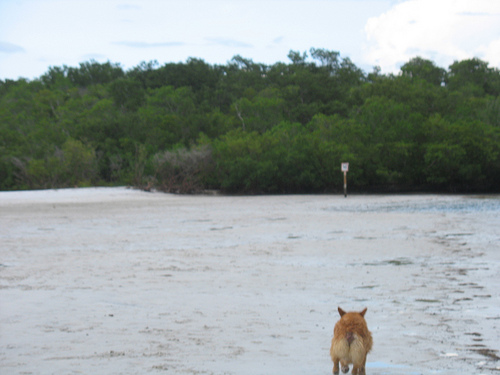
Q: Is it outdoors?
A: Yes, it is outdoors.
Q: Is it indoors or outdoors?
A: It is outdoors.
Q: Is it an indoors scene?
A: No, it is outdoors.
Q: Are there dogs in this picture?
A: Yes, there is a dog.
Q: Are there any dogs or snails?
A: Yes, there is a dog.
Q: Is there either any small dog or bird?
A: Yes, there is a small dog.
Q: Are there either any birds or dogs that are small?
A: Yes, the dog is small.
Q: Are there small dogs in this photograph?
A: Yes, there is a small dog.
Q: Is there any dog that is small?
A: Yes, there is a dog that is small.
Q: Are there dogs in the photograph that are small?
A: Yes, there is a dog that is small.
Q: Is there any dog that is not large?
A: Yes, there is a small dog.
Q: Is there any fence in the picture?
A: No, there are no fences.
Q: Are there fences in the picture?
A: No, there are no fences.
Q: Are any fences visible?
A: No, there are no fences.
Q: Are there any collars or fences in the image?
A: No, there are no fences or collars.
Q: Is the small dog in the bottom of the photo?
A: Yes, the dog is in the bottom of the image.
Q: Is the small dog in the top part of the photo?
A: No, the dog is in the bottom of the image.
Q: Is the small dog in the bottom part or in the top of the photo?
A: The dog is in the bottom of the image.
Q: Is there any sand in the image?
A: Yes, there is sand.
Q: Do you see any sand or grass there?
A: Yes, there is sand.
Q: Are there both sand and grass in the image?
A: No, there is sand but no grass.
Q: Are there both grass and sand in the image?
A: No, there is sand but no grass.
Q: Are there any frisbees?
A: No, there are no frisbees.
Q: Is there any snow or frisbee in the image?
A: No, there are no frisbees or snow.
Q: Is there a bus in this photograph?
A: No, there are no buses.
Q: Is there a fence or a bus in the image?
A: No, there are no buses or fences.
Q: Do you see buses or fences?
A: No, there are no buses or fences.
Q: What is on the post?
A: The sign is on the post.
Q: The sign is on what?
A: The sign is on the post.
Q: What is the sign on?
A: The sign is on the post.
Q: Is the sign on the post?
A: Yes, the sign is on the post.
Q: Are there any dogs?
A: Yes, there is a dog.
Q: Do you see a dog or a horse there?
A: Yes, there is a dog.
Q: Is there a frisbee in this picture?
A: No, there are no frisbees.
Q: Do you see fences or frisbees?
A: No, there are no frisbees or fences.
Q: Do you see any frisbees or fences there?
A: No, there are no frisbees or fences.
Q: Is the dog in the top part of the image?
A: No, the dog is in the bottom of the image.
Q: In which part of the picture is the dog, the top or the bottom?
A: The dog is in the bottom of the image.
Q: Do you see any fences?
A: No, there are no fences.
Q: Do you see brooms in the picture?
A: No, there are no brooms.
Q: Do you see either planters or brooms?
A: No, there are no brooms or planters.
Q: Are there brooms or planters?
A: No, there are no brooms or planters.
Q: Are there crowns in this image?
A: No, there are no crowns.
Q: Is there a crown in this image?
A: No, there are no crowns.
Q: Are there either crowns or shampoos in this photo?
A: No, there are no crowns or shampoos.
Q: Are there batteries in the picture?
A: No, there are no batteries.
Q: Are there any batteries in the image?
A: No, there are no batteries.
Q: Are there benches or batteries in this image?
A: No, there are no batteries or benches.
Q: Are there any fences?
A: No, there are no fences.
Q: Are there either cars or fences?
A: No, there are no fences or cars.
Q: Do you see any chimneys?
A: No, there are no chimneys.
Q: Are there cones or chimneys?
A: No, there are no chimneys or cones.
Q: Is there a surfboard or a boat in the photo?
A: No, there are no surfboards or boats.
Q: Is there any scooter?
A: No, there are no scooters.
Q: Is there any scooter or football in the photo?
A: No, there are no scooters or footballs.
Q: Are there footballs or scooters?
A: No, there are no scooters or footballs.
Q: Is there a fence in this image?
A: No, there are no fences.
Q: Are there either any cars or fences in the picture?
A: No, there are no fences or cars.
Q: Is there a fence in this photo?
A: No, there are no fences.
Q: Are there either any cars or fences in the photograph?
A: No, there are no fences or cars.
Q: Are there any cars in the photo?
A: No, there are no cars.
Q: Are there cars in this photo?
A: No, there are no cars.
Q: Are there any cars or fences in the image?
A: No, there are no cars or fences.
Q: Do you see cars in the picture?
A: No, there are no cars.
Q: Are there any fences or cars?
A: No, there are no cars or fences.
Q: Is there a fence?
A: No, there are no fences.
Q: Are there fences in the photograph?
A: No, there are no fences.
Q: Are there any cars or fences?
A: No, there are no fences or cars.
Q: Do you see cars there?
A: No, there are no cars.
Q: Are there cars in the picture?
A: No, there are no cars.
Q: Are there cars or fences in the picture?
A: No, there are no cars or fences.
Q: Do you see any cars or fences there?
A: No, there are no cars or fences.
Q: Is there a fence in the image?
A: No, there are no fences.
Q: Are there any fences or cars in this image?
A: No, there are no fences or cars.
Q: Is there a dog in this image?
A: Yes, there is a dog.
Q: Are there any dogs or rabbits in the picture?
A: Yes, there is a dog.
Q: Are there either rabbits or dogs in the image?
A: Yes, there is a dog.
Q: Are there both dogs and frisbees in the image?
A: No, there is a dog but no frisbees.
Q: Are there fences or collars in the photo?
A: No, there are no fences or collars.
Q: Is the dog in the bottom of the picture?
A: Yes, the dog is in the bottom of the image.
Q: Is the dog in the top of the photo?
A: No, the dog is in the bottom of the image.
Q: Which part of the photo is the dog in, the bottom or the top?
A: The dog is in the bottom of the image.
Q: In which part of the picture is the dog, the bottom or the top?
A: The dog is in the bottom of the image.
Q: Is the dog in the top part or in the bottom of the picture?
A: The dog is in the bottom of the image.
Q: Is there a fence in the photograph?
A: No, there are no fences.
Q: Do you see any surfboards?
A: No, there are no surfboards.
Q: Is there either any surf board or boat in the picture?
A: No, there are no surfboards or boats.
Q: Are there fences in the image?
A: No, there are no fences.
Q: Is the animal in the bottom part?
A: Yes, the animal is in the bottom of the image.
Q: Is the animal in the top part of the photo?
A: No, the animal is in the bottom of the image.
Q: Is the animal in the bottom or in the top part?
A: The animal is in the bottom of the image.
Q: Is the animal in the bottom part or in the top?
A: The animal is in the bottom of the image.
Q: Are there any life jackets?
A: No, there are no life jackets.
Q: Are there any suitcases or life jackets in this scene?
A: No, there are no life jackets or suitcases.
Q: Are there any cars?
A: No, there are no cars.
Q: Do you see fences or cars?
A: No, there are no cars or fences.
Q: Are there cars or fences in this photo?
A: No, there are no cars or fences.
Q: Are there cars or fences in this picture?
A: No, there are no cars or fences.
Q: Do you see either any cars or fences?
A: No, there are no cars or fences.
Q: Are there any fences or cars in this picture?
A: No, there are no cars or fences.